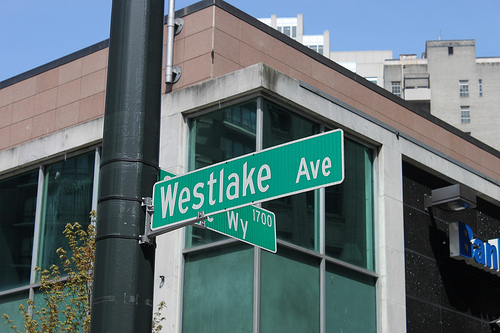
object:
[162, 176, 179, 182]
border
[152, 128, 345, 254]
sign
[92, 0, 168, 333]
pole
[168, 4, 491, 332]
building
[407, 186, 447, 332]
wall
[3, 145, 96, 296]
window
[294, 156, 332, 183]
lettering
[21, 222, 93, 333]
tree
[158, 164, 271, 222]
lettering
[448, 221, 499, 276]
logo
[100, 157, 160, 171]
band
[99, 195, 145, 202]
band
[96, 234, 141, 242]
band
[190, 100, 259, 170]
window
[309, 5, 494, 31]
sky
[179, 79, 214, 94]
mark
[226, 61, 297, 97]
concrete